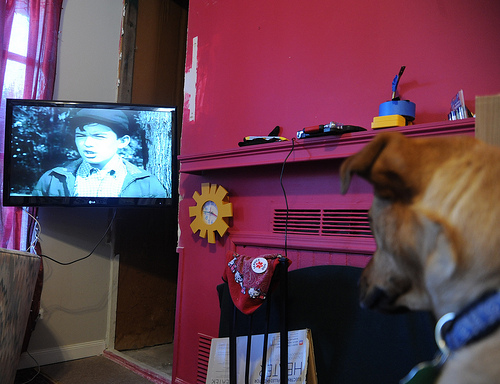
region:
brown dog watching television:
[331, 120, 497, 382]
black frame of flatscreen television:
[1, 95, 176, 208]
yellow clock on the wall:
[182, 176, 240, 246]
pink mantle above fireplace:
[177, 115, 477, 179]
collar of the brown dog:
[428, 280, 498, 353]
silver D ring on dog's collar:
[431, 315, 454, 349]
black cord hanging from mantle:
[268, 143, 299, 316]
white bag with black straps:
[205, 260, 314, 382]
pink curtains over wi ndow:
[1, 0, 53, 247]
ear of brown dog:
[340, 127, 415, 195]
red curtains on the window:
[16, 14, 56, 85]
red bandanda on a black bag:
[209, 250, 291, 318]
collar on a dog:
[419, 300, 499, 362]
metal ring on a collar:
[430, 308, 467, 365]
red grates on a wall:
[265, 193, 371, 245]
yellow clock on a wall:
[188, 183, 234, 251]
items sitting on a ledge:
[235, 119, 367, 147]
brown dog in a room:
[329, 126, 498, 383]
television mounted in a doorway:
[8, 87, 177, 215]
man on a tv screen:
[41, 113, 150, 181]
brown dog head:
[324, 131, 499, 321]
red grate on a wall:
[262, 196, 390, 260]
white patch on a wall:
[176, 32, 219, 144]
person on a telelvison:
[56, 111, 155, 193]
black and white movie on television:
[13, 106, 172, 204]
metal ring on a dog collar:
[429, 308, 467, 356]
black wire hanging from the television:
[23, 226, 123, 286]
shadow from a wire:
[37, 285, 112, 322]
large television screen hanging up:
[5, 102, 179, 211]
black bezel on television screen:
[0, 98, 175, 108]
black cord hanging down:
[50, 211, 127, 271]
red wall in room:
[209, 0, 386, 91]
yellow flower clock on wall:
[187, 180, 229, 245]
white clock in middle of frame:
[197, 200, 219, 226]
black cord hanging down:
[267, 140, 305, 223]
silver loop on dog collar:
[417, 311, 462, 366]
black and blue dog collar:
[429, 292, 496, 354]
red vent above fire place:
[260, 200, 367, 234]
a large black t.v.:
[4, 96, 182, 211]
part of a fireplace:
[224, 235, 439, 382]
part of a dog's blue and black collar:
[418, 288, 498, 359]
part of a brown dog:
[335, 125, 492, 382]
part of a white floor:
[117, 338, 172, 373]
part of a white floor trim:
[15, 335, 106, 367]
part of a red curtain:
[0, 1, 57, 256]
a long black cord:
[270, 138, 298, 344]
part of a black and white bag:
[206, 324, 321, 381]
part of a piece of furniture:
[0, 242, 41, 382]